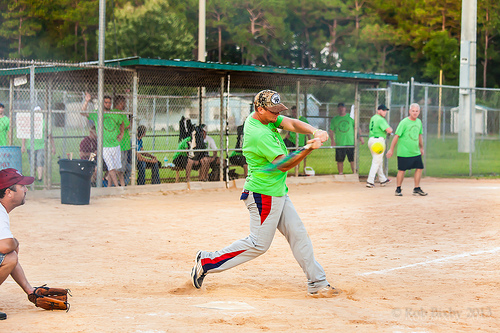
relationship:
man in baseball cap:
[190, 87, 348, 298] [253, 90, 288, 114]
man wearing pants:
[190, 87, 348, 298] [201, 181, 330, 288]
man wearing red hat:
[2, 167, 41, 314] [0, 165, 35, 190]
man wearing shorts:
[378, 98, 431, 197] [382, 143, 434, 172]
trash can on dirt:
[57, 158, 97, 204] [0, 177, 499, 332]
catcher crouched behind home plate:
[4, 166, 79, 323] [192, 292, 255, 314]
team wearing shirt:
[80, 83, 438, 306] [241, 110, 290, 200]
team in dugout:
[91, 95, 236, 175] [133, 61, 223, 153]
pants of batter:
[201, 190, 329, 292] [190, 87, 345, 299]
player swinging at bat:
[184, 82, 351, 296] [269, 143, 324, 175]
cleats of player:
[178, 245, 351, 300] [184, 82, 351, 296]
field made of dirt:
[0, 144, 498, 330] [117, 195, 423, 326]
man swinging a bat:
[173, 84, 351, 296] [261, 142, 338, 179]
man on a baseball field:
[173, 84, 351, 296] [4, 176, 496, 328]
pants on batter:
[201, 190, 329, 292] [190, 87, 345, 299]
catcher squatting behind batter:
[1, 166, 54, 322] [176, 83, 337, 300]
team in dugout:
[81, 87, 230, 190] [74, 72, 352, 177]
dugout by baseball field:
[74, 72, 352, 177] [4, 176, 496, 328]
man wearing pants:
[178, 79, 340, 307] [181, 77, 349, 302]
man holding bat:
[190, 87, 348, 298] [276, 142, 310, 170]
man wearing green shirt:
[190, 87, 348, 298] [241, 110, 290, 196]